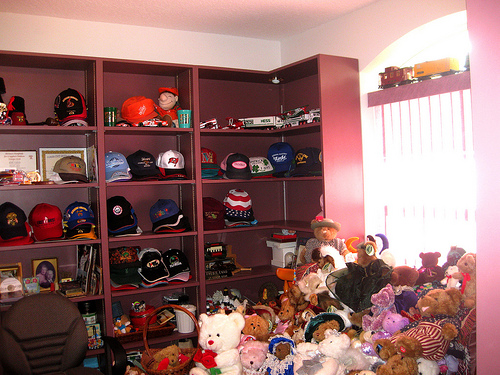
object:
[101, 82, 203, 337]
ball caps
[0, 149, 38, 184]
certificates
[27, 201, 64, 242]
red hat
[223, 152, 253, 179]
hat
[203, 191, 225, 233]
hat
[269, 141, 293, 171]
hat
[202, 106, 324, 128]
toys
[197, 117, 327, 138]
shelf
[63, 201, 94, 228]
hat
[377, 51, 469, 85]
train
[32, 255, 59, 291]
photo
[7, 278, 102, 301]
shelf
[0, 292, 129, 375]
chair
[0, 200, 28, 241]
cap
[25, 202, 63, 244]
cap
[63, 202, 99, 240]
cap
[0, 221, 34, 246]
cap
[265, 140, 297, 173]
hat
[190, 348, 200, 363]
flower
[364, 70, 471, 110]
shelf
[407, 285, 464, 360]
bear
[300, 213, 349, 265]
teddy bear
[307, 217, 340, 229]
hat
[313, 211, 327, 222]
flower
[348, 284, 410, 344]
teddy bears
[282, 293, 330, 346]
teddy bears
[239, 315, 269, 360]
teddy bears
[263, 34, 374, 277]
corner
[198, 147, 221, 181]
cap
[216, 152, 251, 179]
cap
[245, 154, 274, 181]
cap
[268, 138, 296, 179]
cap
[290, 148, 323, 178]
cap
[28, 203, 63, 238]
hat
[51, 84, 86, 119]
hat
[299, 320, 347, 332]
doll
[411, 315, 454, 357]
clothing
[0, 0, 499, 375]
room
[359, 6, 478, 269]
window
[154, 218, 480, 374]
stuffed animals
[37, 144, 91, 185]
certificate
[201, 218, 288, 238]
shelf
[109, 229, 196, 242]
shelf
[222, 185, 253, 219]
hat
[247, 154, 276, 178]
hat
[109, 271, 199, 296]
shelf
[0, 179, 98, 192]
shelf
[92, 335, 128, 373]
armrest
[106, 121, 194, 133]
shelf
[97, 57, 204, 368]
bookcase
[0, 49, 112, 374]
bookcase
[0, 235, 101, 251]
shelf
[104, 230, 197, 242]
shelf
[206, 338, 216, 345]
nose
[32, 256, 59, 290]
frame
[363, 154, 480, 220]
sunlight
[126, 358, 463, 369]
floor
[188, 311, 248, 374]
bear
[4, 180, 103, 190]
shelf